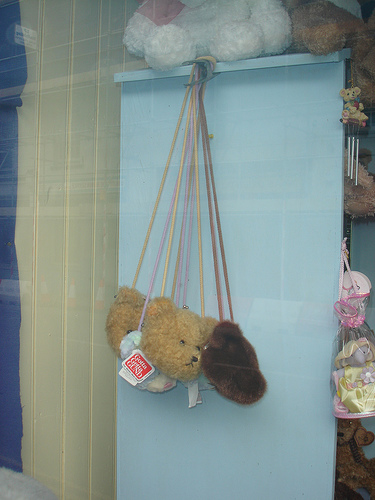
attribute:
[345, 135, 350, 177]
chime — hanging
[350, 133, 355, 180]
chime — hanging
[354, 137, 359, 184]
chime — hanging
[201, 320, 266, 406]
purse — hanging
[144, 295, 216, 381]
purse — hanging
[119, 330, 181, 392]
purse — hanging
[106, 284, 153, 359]
purse — hanging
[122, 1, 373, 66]
animals — stuffed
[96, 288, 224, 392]
teddy bear — hanging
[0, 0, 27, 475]
curtain — blue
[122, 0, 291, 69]
teddy bear — white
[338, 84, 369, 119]
bear — small, seated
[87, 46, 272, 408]
purses — hanging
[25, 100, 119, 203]
wall — yellow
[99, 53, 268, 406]
windchime — hanging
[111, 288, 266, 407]
purse — furry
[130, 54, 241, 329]
rope — holding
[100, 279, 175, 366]
purse — hanging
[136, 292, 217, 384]
purse — hanging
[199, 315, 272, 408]
purse — hanging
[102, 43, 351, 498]
shelf unit — light blue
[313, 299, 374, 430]
animal — stuffed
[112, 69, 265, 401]
purses — hanging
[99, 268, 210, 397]
animal — stuffed